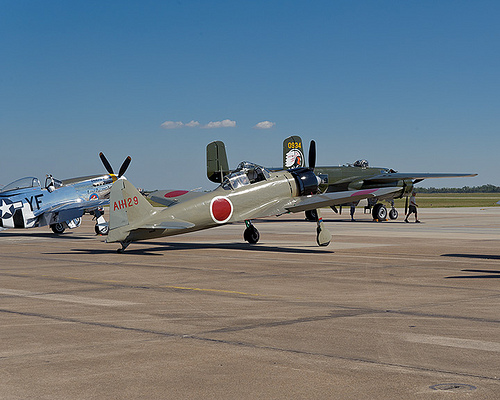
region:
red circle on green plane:
[187, 190, 270, 252]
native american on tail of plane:
[271, 125, 313, 170]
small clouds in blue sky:
[152, 102, 274, 136]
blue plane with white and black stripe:
[6, 145, 125, 236]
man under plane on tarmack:
[403, 181, 436, 230]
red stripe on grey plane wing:
[294, 181, 406, 212]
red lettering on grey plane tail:
[95, 184, 159, 223]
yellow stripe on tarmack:
[158, 266, 278, 311]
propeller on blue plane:
[86, 145, 143, 205]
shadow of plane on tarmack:
[83, 221, 338, 273]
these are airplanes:
[39, 59, 416, 314]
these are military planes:
[69, 140, 369, 307]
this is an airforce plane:
[61, 149, 355, 291]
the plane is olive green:
[119, 171, 333, 276]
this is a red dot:
[198, 190, 250, 226]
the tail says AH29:
[99, 186, 172, 221]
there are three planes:
[17, 132, 420, 300]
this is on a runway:
[34, 122, 470, 397]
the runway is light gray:
[81, 276, 344, 370]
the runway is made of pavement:
[24, 244, 404, 379]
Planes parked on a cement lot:
[1, 134, 477, 244]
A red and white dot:
[209, 195, 235, 222]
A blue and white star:
[0, 200, 17, 217]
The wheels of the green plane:
[244, 222, 331, 246]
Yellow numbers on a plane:
[287, 140, 299, 150]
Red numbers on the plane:
[112, 196, 137, 211]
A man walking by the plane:
[404, 190, 423, 224]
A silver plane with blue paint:
[0, 152, 134, 234]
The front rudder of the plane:
[97, 152, 135, 184]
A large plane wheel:
[372, 201, 387, 220]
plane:
[88, 151, 330, 261]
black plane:
[318, 136, 445, 226]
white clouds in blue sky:
[32, 19, 72, 49]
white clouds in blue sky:
[425, 9, 477, 67]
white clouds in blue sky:
[325, 99, 376, 139]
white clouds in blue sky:
[301, 35, 382, 75]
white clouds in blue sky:
[204, 59, 272, 87]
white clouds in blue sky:
[132, 22, 212, 56]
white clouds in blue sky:
[127, 53, 194, 101]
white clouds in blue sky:
[61, 42, 118, 72]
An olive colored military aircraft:
[100, 145, 362, 247]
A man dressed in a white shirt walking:
[402, 193, 427, 226]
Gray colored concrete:
[270, 308, 470, 378]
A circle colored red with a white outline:
[207, 195, 234, 225]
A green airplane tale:
[202, 138, 228, 177]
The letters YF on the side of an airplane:
[6, 179, 53, 213]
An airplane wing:
[277, 185, 403, 207]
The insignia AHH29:
[104, 194, 146, 212]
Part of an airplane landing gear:
[312, 213, 336, 248]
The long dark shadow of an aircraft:
[163, 238, 312, 256]